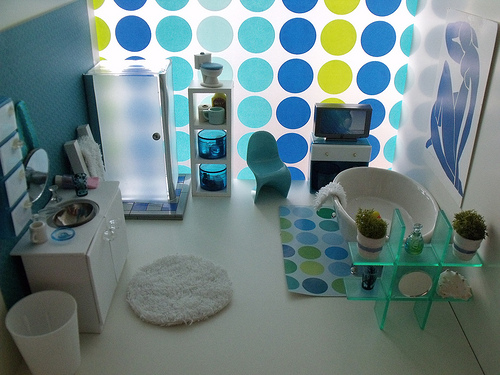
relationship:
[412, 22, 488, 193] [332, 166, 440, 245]
painting behind mini bath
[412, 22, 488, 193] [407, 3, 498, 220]
painting on wall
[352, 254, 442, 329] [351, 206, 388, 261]
glass shelf has plants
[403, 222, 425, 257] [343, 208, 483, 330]
vase atop glass shelf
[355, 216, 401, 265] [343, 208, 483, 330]
plants on glass shelf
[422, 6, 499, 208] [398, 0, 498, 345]
painting on wall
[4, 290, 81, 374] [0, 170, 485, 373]
trash bin on floor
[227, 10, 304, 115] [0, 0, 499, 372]
glass wall of bathroom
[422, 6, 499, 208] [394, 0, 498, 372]
painting on wall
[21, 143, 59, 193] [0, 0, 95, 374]
mirror on wall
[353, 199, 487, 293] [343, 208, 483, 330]
plants on glass shelf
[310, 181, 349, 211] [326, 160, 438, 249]
towel draped over tub